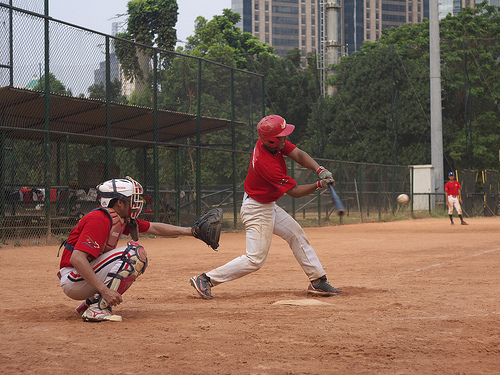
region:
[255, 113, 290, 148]
red batting helmet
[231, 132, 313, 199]
man wears red shirt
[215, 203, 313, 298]
man wears grey slacks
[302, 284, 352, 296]
man wears black shoes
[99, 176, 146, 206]
catcher wears white helmet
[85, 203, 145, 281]
catcher wears red chest guard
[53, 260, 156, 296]
catcher wears white pants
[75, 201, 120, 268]
catcher wears red shirt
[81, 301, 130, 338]
catcher wears white shoes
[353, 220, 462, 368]
dirt is brown on field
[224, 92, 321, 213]
man on red shirt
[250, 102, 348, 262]
man on red shirt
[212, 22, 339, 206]
man on red shirt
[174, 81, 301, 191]
man on red shirt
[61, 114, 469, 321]
the players playing baseball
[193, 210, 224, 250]
the black catchers mitt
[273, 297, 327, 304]
the home plate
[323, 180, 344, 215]
the black bat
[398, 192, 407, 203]
the baseball in motion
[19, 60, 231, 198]
the green fence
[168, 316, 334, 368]
the dirt on the ground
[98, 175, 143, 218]
the catchers mask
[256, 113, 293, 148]
the batter's red helmet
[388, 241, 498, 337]
the fading white lines on the field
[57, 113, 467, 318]
the baseball players on the field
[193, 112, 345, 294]
the batter hitting the ball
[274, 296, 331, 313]
the base home plate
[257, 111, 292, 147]
the batter's helmet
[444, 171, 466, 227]
the player out in the field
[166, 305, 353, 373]
the dirt on the field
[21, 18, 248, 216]
the green wired fence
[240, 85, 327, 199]
man wearing red helmet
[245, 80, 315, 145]
man wearing red helmet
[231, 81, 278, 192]
man wearing red helmet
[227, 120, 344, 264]
man wearing red helmet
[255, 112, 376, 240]
man wearing red helmet